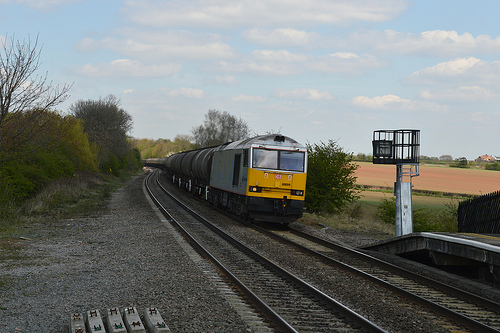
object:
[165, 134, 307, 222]
train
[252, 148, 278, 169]
window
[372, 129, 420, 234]
lift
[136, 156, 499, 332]
tracks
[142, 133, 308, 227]
car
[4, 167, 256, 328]
stones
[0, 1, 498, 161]
sky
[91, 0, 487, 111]
clouds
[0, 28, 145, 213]
bushes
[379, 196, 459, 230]
grass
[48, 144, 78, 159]
leaves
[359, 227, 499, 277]
ramp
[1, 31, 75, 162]
tree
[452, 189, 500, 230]
fence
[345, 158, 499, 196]
field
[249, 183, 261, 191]
headlight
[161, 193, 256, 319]
track